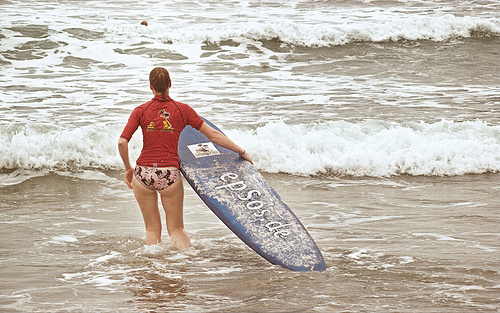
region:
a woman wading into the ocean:
[112, 67, 256, 254]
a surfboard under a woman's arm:
[176, 112, 326, 274]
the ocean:
[0, 0, 498, 312]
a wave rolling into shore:
[2, 21, 498, 168]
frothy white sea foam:
[227, 126, 498, 179]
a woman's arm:
[119, 109, 142, 183]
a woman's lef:
[130, 169, 164, 251]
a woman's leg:
[158, 170, 192, 258]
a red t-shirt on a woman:
[119, 94, 203, 171]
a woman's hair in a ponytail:
[147, 67, 171, 97]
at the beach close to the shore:
[5, 3, 494, 308]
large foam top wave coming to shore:
[2, 26, 498, 56]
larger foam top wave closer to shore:
[2, 121, 497, 177]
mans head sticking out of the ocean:
[139, 21, 149, 28]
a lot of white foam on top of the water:
[5, 43, 491, 118]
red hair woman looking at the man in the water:
[116, 65, 327, 274]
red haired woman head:
[147, 68, 172, 99]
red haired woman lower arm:
[115, 138, 135, 186]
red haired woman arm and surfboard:
[179, 103, 351, 274]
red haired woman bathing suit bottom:
[131, 164, 183, 191]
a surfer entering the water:
[85, 64, 337, 282]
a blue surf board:
[181, 110, 321, 290]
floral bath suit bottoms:
[127, 161, 184, 199]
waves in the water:
[297, 113, 482, 194]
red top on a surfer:
[119, 91, 204, 175]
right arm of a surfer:
[179, 84, 275, 204]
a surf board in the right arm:
[174, 96, 256, 196]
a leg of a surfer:
[140, 176, 154, 266]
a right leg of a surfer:
[164, 172, 186, 268]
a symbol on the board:
[190, 134, 220, 169]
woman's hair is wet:
[120, 55, 180, 104]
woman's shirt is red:
[126, 101, 202, 169]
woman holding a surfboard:
[106, 51, 324, 277]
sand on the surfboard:
[179, 153, 319, 273]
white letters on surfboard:
[208, 156, 318, 251]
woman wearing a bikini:
[125, 160, 178, 196]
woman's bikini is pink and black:
[123, 150, 199, 206]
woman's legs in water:
[142, 223, 211, 273]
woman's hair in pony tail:
[137, 53, 174, 106]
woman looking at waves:
[74, 40, 259, 266]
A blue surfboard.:
[164, 101, 337, 277]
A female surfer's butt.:
[127, 162, 182, 199]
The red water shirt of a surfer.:
[117, 91, 206, 171]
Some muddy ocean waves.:
[0, 5, 498, 181]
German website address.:
[212, 164, 294, 246]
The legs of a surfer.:
[128, 185, 193, 255]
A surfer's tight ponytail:
[153, 71, 170, 103]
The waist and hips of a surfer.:
[127, 129, 187, 196]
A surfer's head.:
[145, 66, 172, 100]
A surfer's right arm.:
[180, 97, 255, 167]